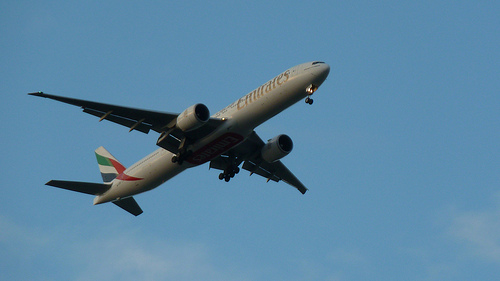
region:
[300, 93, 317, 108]
Front black wheels of the plane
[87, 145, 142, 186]
Colorful tail wing of the plane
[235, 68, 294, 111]
"Emirates" printed on the side of the plane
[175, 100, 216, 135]
Right plane engine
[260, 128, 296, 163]
Left plane engine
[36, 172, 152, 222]
Tail wings of the plane on either side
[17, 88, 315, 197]
Main wings of the plane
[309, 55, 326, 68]
Front window of the plane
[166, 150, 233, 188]
Wheels underneath the plane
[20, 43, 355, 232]
Plane flying up into the sky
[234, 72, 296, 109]
name of airline on side of plane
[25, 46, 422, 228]
plane in the air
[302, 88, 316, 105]
landing gear down on the front of the plane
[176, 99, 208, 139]
engine on the right side of the plane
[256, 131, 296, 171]
engine under the left wing of the plane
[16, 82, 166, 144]
wing with the flaps down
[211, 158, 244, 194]
landing gear under the wings down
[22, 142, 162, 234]
tail wing of the plane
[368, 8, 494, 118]
bright blue clear sky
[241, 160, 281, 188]
flap on the wing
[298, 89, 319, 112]
Front wheel of passenger jet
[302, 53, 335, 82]
Cockpit of passenger jet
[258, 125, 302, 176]
left engine of passenger jet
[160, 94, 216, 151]
right engine of passenger jet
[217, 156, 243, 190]
left rear wheel of passenger jet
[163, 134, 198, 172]
right rear wheel of passenger jet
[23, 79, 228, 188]
right wing of passenger jet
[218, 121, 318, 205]
right wing of passenger jet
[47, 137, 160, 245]
Tail section of passenger jet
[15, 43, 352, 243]
Passenger jet in flight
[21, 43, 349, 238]
the plane is gray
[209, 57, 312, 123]
red letters on plane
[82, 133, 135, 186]
plane's tail is red white blue and green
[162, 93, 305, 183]
1 engine on each side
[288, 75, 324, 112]
plane wheels are out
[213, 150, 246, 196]
plane wheels are out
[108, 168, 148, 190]
red shape on plane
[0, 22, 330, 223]
plane is in air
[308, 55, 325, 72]
black window on plane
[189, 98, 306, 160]
circular holes in engine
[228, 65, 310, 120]
an emirates airline plane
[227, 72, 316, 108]
a plant with red lettering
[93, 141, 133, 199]
a plant tail with green red and black markings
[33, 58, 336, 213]
a plane flying in the air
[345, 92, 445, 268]
clear blue sky above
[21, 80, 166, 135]
a airplanes wing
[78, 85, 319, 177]
a pair of airplane wings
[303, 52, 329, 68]
the cockpit of a plane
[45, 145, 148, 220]
the tail of an airplane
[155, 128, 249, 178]
a pair of airplane wheels